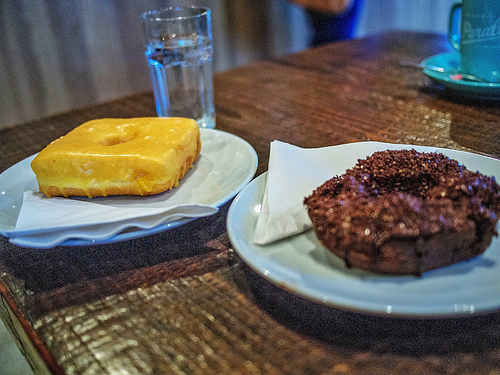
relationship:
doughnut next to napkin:
[37, 109, 201, 191] [13, 185, 215, 255]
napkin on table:
[11, 168, 218, 246] [5, 24, 496, 374]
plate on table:
[225, 144, 495, 322] [5, 24, 496, 374]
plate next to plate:
[1, 126, 258, 249] [225, 144, 495, 322]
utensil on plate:
[426, 49, 468, 117] [419, 47, 459, 65]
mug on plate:
[443, 0, 498, 85] [421, 47, 499, 97]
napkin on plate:
[273, 149, 303, 232] [225, 144, 495, 322]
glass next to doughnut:
[134, 1, 222, 127] [29, 115, 202, 204]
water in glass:
[142, 30, 217, 131] [134, 1, 222, 127]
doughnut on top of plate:
[29, 115, 202, 204] [1, 126, 258, 249]